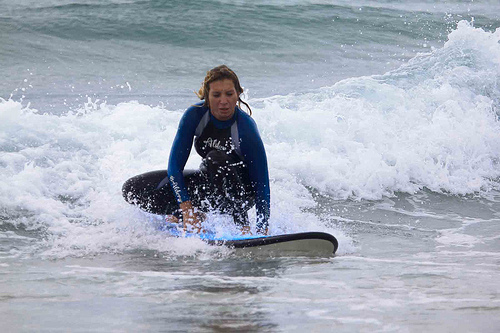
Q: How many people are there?
A: One.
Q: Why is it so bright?
A: Sun light.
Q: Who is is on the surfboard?
A: The woman.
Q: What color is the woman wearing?
A: Blue.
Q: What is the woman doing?
A: Surfing.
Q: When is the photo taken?
A: Day time.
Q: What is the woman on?
A: The surfboard.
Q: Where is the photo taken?
A: In the ocean.